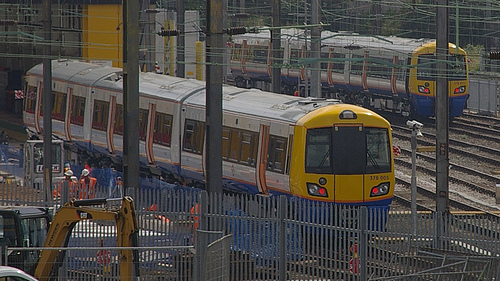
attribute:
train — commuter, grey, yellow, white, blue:
[16, 52, 402, 252]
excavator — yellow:
[3, 192, 145, 279]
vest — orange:
[79, 176, 98, 196]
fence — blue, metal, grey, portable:
[7, 175, 498, 277]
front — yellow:
[291, 104, 399, 257]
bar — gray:
[203, 2, 229, 278]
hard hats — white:
[64, 168, 91, 176]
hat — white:
[79, 166, 90, 177]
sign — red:
[13, 85, 26, 104]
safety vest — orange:
[144, 213, 168, 225]